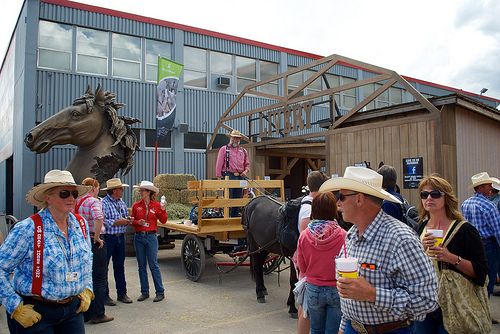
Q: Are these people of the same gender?
A: No, they are both male and female.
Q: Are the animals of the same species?
A: Yes, all the animals are horses.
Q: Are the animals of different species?
A: No, all the animals are horses.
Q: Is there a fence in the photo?
A: No, there are no fences.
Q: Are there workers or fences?
A: No, there are no fences or workers.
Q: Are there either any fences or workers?
A: No, there are no fences or workers.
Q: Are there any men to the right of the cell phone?
A: Yes, there is a man to the right of the cell phone.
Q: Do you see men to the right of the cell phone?
A: Yes, there is a man to the right of the cell phone.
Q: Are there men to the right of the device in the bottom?
A: Yes, there is a man to the right of the cell phone.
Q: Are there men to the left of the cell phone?
A: No, the man is to the right of the cell phone.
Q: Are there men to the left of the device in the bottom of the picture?
A: No, the man is to the right of the cell phone.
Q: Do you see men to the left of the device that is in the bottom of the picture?
A: No, the man is to the right of the cell phone.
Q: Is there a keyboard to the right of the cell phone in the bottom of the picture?
A: No, there is a man to the right of the mobile phone.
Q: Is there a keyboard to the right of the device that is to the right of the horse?
A: No, there is a man to the right of the mobile phone.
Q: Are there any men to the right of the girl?
A: Yes, there is a man to the right of the girl.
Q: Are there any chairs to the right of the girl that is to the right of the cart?
A: No, there is a man to the right of the girl.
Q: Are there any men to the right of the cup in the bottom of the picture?
A: Yes, there is a man to the right of the cup.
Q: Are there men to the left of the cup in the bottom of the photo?
A: No, the man is to the right of the cup.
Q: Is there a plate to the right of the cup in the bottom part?
A: No, there is a man to the right of the cup.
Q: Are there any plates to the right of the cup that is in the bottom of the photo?
A: No, there is a man to the right of the cup.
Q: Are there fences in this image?
A: No, there are no fences.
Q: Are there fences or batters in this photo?
A: No, there are no fences or batters.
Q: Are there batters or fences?
A: No, there are no fences or batters.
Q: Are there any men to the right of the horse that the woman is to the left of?
A: Yes, there is a man to the right of the horse.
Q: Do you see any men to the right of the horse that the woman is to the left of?
A: Yes, there is a man to the right of the horse.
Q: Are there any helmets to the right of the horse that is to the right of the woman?
A: No, there is a man to the right of the horse.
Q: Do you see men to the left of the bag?
A: Yes, there is a man to the left of the bag.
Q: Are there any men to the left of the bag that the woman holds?
A: Yes, there is a man to the left of the bag.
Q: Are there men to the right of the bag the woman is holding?
A: No, the man is to the left of the bag.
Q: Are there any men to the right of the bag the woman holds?
A: No, the man is to the left of the bag.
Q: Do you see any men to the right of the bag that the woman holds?
A: No, the man is to the left of the bag.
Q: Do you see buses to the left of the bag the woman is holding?
A: No, there is a man to the left of the bag.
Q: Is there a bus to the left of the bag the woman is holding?
A: No, there is a man to the left of the bag.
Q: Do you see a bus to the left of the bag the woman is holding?
A: No, there is a man to the left of the bag.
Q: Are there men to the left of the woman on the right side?
A: Yes, there is a man to the left of the woman.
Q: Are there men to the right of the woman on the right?
A: No, the man is to the left of the woman.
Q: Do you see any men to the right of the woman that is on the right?
A: No, the man is to the left of the woman.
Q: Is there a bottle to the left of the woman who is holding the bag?
A: No, there is a man to the left of the woman.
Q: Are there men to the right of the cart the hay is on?
A: Yes, there is a man to the right of the cart.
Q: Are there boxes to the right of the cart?
A: No, there is a man to the right of the cart.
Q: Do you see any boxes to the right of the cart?
A: No, there is a man to the right of the cart.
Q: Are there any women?
A: Yes, there is a woman.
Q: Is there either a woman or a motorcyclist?
A: Yes, there is a woman.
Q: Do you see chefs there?
A: No, there are no chefs.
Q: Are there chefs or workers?
A: No, there are no chefs or workers.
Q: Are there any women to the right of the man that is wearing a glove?
A: Yes, there is a woman to the right of the man.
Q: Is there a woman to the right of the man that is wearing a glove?
A: Yes, there is a woman to the right of the man.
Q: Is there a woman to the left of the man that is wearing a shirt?
A: No, the woman is to the right of the man.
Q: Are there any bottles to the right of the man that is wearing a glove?
A: No, there is a woman to the right of the man.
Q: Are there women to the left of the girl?
A: Yes, there is a woman to the left of the girl.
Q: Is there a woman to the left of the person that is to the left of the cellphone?
A: Yes, there is a woman to the left of the girl.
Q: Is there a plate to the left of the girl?
A: No, there is a woman to the left of the girl.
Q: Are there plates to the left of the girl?
A: No, there is a woman to the left of the girl.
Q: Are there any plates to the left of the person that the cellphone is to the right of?
A: No, there is a woman to the left of the girl.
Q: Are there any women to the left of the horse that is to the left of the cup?
A: Yes, there is a woman to the left of the horse.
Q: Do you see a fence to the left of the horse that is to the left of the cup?
A: No, there is a woman to the left of the horse.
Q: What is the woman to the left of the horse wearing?
A: The woman is wearing a shirt.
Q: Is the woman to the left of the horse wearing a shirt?
A: Yes, the woman is wearing a shirt.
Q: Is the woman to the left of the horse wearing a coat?
A: No, the woman is wearing a shirt.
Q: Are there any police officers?
A: No, there are no police officers.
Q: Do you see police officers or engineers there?
A: No, there are no police officers or engineers.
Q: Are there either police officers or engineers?
A: No, there are no police officers or engineers.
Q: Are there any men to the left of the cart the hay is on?
A: Yes, there is a man to the left of the cart.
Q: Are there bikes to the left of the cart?
A: No, there is a man to the left of the cart.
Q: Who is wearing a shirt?
A: The man is wearing a shirt.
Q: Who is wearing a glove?
A: The man is wearing a glove.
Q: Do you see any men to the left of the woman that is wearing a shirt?
A: Yes, there is a man to the left of the woman.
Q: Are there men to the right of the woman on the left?
A: No, the man is to the left of the woman.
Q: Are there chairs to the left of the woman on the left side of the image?
A: No, there is a man to the left of the woman.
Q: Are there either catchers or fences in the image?
A: No, there are no fences or catchers.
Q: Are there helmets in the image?
A: No, there are no helmets.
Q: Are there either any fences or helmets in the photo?
A: No, there are no helmets or fences.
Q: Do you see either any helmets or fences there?
A: No, there are no helmets or fences.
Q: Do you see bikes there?
A: No, there are no bikes.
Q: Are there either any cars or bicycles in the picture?
A: No, there are no bicycles or cars.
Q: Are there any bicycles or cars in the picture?
A: No, there are no bicycles or cars.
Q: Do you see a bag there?
A: Yes, there is a bag.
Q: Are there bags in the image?
A: Yes, there is a bag.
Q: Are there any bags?
A: Yes, there is a bag.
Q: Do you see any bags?
A: Yes, there is a bag.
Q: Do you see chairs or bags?
A: Yes, there is a bag.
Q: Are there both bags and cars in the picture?
A: No, there is a bag but no cars.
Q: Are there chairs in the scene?
A: No, there are no chairs.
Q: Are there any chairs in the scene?
A: No, there are no chairs.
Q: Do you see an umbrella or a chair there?
A: No, there are no chairs or umbrellas.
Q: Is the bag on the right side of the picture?
A: Yes, the bag is on the right of the image.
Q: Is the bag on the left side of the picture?
A: No, the bag is on the right of the image.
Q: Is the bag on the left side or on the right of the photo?
A: The bag is on the right of the image.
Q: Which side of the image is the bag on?
A: The bag is on the right of the image.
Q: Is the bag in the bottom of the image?
A: Yes, the bag is in the bottom of the image.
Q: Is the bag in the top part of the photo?
A: No, the bag is in the bottom of the image.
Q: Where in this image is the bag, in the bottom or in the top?
A: The bag is in the bottom of the image.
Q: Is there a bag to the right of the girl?
A: Yes, there is a bag to the right of the girl.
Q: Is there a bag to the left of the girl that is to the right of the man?
A: No, the bag is to the right of the girl.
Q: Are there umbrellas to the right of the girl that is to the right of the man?
A: No, there is a bag to the right of the girl.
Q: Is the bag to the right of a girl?
A: Yes, the bag is to the right of a girl.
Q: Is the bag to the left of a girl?
A: No, the bag is to the right of a girl.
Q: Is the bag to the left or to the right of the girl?
A: The bag is to the right of the girl.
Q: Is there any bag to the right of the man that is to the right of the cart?
A: Yes, there is a bag to the right of the man.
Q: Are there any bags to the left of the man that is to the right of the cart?
A: No, the bag is to the right of the man.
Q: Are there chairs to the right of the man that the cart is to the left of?
A: No, there is a bag to the right of the man.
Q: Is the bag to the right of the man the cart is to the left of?
A: Yes, the bag is to the right of the man.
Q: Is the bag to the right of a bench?
A: No, the bag is to the right of the man.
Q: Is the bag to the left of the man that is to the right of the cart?
A: No, the bag is to the right of the man.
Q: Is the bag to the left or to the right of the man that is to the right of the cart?
A: The bag is to the right of the man.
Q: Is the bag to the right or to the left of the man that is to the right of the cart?
A: The bag is to the right of the man.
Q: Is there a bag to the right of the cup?
A: Yes, there is a bag to the right of the cup.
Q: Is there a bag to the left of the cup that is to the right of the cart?
A: No, the bag is to the right of the cup.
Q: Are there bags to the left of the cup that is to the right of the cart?
A: No, the bag is to the right of the cup.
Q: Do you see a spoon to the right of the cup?
A: No, there is a bag to the right of the cup.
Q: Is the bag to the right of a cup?
A: Yes, the bag is to the right of a cup.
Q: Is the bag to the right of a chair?
A: No, the bag is to the right of a cup.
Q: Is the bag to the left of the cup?
A: No, the bag is to the right of the cup.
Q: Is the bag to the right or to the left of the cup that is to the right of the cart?
A: The bag is to the right of the cup.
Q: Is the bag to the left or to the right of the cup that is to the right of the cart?
A: The bag is to the right of the cup.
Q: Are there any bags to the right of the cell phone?
A: Yes, there is a bag to the right of the cell phone.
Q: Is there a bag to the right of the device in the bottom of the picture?
A: Yes, there is a bag to the right of the cell phone.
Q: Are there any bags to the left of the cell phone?
A: No, the bag is to the right of the cell phone.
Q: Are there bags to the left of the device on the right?
A: No, the bag is to the right of the cell phone.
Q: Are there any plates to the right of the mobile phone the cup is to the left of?
A: No, there is a bag to the right of the mobile phone.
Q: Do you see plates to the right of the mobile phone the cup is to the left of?
A: No, there is a bag to the right of the mobile phone.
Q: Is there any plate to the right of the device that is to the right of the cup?
A: No, there is a bag to the right of the mobile phone.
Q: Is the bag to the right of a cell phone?
A: Yes, the bag is to the right of a cell phone.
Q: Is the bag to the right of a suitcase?
A: No, the bag is to the right of a cell phone.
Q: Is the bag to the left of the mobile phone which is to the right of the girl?
A: No, the bag is to the right of the cellphone.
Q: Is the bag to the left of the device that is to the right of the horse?
A: No, the bag is to the right of the cellphone.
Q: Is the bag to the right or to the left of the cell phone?
A: The bag is to the right of the cell phone.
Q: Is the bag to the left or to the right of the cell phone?
A: The bag is to the right of the cell phone.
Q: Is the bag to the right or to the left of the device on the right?
A: The bag is to the right of the cell phone.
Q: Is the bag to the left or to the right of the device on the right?
A: The bag is to the right of the cell phone.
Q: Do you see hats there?
A: Yes, there is a hat.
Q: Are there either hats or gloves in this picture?
A: Yes, there is a hat.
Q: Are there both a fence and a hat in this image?
A: No, there is a hat but no fences.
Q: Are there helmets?
A: No, there are no helmets.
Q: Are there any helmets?
A: No, there are no helmets.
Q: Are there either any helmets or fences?
A: No, there are no helmets or fences.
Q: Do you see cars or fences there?
A: No, there are no fences or cars.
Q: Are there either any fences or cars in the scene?
A: No, there are no fences or cars.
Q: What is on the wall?
A: The sign is on the wall.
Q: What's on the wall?
A: The sign is on the wall.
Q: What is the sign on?
A: The sign is on the wall.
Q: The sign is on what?
A: The sign is on the wall.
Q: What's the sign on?
A: The sign is on the wall.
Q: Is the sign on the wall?
A: Yes, the sign is on the wall.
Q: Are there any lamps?
A: No, there are no lamps.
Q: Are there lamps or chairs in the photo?
A: No, there are no lamps or chairs.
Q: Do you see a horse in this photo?
A: Yes, there is a horse.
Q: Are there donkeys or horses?
A: Yes, there is a horse.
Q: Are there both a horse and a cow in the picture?
A: No, there is a horse but no cows.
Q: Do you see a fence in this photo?
A: No, there are no fences.